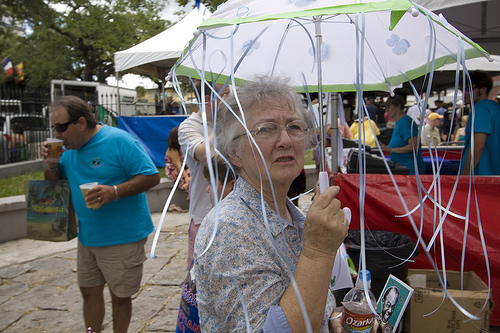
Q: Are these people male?
A: No, they are both male and female.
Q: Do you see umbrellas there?
A: Yes, there is an umbrella.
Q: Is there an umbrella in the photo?
A: Yes, there is an umbrella.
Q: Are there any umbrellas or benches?
A: Yes, there is an umbrella.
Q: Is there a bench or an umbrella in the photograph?
A: Yes, there is an umbrella.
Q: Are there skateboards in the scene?
A: No, there are no skateboards.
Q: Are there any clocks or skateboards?
A: No, there are no skateboards or clocks.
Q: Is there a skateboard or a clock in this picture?
A: No, there are no skateboards or clocks.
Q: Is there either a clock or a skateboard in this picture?
A: No, there are no skateboards or clocks.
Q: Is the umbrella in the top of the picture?
A: Yes, the umbrella is in the top of the image.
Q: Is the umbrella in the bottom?
A: No, the umbrella is in the top of the image.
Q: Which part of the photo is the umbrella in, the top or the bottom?
A: The umbrella is in the top of the image.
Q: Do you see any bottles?
A: Yes, there is a bottle.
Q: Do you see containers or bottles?
A: Yes, there is a bottle.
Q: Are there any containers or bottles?
A: Yes, there is a bottle.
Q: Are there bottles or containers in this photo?
A: Yes, there is a bottle.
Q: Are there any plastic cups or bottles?
A: Yes, there is a plastic bottle.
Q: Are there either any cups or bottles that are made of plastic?
A: Yes, the bottle is made of plastic.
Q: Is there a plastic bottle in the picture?
A: Yes, there is a bottle that is made of plastic.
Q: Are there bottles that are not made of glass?
A: Yes, there is a bottle that is made of plastic.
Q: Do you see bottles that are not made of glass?
A: Yes, there is a bottle that is made of plastic.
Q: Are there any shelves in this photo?
A: No, there are no shelves.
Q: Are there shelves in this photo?
A: No, there are no shelves.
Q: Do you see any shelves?
A: No, there are no shelves.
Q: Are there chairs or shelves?
A: No, there are no shelves or chairs.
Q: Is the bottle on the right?
A: Yes, the bottle is on the right of the image.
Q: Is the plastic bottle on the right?
A: Yes, the bottle is on the right of the image.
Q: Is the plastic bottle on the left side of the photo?
A: No, the bottle is on the right of the image.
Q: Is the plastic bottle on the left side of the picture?
A: No, the bottle is on the right of the image.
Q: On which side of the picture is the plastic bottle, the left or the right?
A: The bottle is on the right of the image.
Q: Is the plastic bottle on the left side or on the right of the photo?
A: The bottle is on the right of the image.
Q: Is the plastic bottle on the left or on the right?
A: The bottle is on the right of the image.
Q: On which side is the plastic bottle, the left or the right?
A: The bottle is on the right of the image.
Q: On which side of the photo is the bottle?
A: The bottle is on the right of the image.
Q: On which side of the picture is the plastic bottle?
A: The bottle is on the right of the image.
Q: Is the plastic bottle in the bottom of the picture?
A: Yes, the bottle is in the bottom of the image.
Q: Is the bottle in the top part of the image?
A: No, the bottle is in the bottom of the image.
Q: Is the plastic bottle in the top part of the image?
A: No, the bottle is in the bottom of the image.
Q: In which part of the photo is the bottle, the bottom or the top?
A: The bottle is in the bottom of the image.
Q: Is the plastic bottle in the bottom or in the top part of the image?
A: The bottle is in the bottom of the image.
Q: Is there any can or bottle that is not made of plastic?
A: No, there is a bottle but it is made of plastic.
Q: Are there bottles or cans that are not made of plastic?
A: No, there is a bottle but it is made of plastic.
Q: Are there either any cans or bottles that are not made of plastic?
A: No, there is a bottle but it is made of plastic.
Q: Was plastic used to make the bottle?
A: Yes, the bottle is made of plastic.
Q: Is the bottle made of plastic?
A: Yes, the bottle is made of plastic.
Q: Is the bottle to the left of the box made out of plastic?
A: Yes, the bottle is made of plastic.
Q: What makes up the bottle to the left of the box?
A: The bottle is made of plastic.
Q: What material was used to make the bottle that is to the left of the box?
A: The bottle is made of plastic.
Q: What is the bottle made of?
A: The bottle is made of plastic.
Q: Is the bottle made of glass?
A: No, the bottle is made of plastic.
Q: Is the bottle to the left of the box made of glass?
A: No, the bottle is made of plastic.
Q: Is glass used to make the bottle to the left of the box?
A: No, the bottle is made of plastic.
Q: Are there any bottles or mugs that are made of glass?
A: No, there is a bottle but it is made of plastic.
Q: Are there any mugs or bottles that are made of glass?
A: No, there is a bottle but it is made of plastic.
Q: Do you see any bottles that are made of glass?
A: No, there is a bottle but it is made of plastic.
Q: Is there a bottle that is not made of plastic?
A: No, there is a bottle but it is made of plastic.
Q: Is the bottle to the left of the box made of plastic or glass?
A: The bottle is made of plastic.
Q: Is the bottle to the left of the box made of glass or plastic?
A: The bottle is made of plastic.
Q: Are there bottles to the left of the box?
A: Yes, there is a bottle to the left of the box.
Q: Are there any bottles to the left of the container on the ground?
A: Yes, there is a bottle to the left of the box.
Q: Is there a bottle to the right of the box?
A: No, the bottle is to the left of the box.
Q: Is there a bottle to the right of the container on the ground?
A: No, the bottle is to the left of the box.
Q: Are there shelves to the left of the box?
A: No, there is a bottle to the left of the box.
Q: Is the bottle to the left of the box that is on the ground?
A: Yes, the bottle is to the left of the box.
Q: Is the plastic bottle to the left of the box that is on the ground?
A: Yes, the bottle is to the left of the box.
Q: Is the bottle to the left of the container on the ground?
A: Yes, the bottle is to the left of the box.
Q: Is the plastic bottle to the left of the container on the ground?
A: Yes, the bottle is to the left of the box.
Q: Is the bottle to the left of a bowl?
A: No, the bottle is to the left of the box.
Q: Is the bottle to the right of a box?
A: No, the bottle is to the left of a box.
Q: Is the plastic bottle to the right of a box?
A: No, the bottle is to the left of a box.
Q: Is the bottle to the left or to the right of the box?
A: The bottle is to the left of the box.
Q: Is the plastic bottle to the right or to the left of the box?
A: The bottle is to the left of the box.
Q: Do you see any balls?
A: No, there are no balls.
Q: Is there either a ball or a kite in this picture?
A: No, there are no balls or kites.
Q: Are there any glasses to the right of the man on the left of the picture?
A: Yes, there are glasses to the right of the man.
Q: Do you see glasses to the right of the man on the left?
A: Yes, there are glasses to the right of the man.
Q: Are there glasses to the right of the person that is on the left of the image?
A: Yes, there are glasses to the right of the man.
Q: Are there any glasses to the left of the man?
A: No, the glasses are to the right of the man.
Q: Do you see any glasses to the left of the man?
A: No, the glasses are to the right of the man.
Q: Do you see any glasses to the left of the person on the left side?
A: No, the glasses are to the right of the man.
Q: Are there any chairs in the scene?
A: No, there are no chairs.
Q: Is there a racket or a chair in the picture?
A: No, there are no chairs or rackets.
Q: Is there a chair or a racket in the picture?
A: No, there are no chairs or rackets.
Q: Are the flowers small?
A: Yes, the flowers are small.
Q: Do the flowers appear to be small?
A: Yes, the flowers are small.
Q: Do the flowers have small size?
A: Yes, the flowers are small.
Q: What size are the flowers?
A: The flowers are small.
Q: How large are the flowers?
A: The flowers are small.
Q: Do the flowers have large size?
A: No, the flowers are small.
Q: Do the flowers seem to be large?
A: No, the flowers are small.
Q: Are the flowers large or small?
A: The flowers are small.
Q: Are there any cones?
A: No, there are no cones.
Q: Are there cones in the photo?
A: No, there are no cones.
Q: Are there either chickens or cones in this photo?
A: No, there are no cones or chickens.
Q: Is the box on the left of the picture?
A: No, the box is on the right of the image.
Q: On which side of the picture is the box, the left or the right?
A: The box is on the right of the image.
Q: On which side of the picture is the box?
A: The box is on the right of the image.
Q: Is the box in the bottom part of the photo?
A: Yes, the box is in the bottom of the image.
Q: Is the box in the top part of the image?
A: No, the box is in the bottom of the image.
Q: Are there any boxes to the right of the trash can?
A: Yes, there is a box to the right of the trash can.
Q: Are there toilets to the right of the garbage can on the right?
A: No, there is a box to the right of the trash bin.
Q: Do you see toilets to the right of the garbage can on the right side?
A: No, there is a box to the right of the trash bin.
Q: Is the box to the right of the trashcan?
A: Yes, the box is to the right of the trashcan.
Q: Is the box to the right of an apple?
A: No, the box is to the right of the trashcan.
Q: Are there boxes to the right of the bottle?
A: Yes, there is a box to the right of the bottle.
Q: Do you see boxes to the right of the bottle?
A: Yes, there is a box to the right of the bottle.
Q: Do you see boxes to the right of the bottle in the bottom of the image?
A: Yes, there is a box to the right of the bottle.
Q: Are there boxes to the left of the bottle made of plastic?
A: No, the box is to the right of the bottle.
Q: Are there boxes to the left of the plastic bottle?
A: No, the box is to the right of the bottle.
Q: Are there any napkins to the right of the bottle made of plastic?
A: No, there is a box to the right of the bottle.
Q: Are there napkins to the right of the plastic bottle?
A: No, there is a box to the right of the bottle.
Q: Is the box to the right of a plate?
A: No, the box is to the right of the bottle.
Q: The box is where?
A: The box is on the ground.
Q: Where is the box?
A: The box is on the ground.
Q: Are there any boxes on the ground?
A: Yes, there is a box on the ground.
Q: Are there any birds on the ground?
A: No, there is a box on the ground.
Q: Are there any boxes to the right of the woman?
A: Yes, there is a box to the right of the woman.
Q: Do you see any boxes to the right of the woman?
A: Yes, there is a box to the right of the woman.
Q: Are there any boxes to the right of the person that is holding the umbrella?
A: Yes, there is a box to the right of the woman.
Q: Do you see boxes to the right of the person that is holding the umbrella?
A: Yes, there is a box to the right of the woman.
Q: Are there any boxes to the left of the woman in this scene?
A: No, the box is to the right of the woman.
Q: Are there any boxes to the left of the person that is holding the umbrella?
A: No, the box is to the right of the woman.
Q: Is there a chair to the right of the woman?
A: No, there is a box to the right of the woman.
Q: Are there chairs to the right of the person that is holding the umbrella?
A: No, there is a box to the right of the woman.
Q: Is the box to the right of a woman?
A: Yes, the box is to the right of a woman.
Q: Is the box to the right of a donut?
A: No, the box is to the right of a woman.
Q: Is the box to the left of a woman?
A: No, the box is to the right of a woman.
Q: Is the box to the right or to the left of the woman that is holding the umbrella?
A: The box is to the right of the woman.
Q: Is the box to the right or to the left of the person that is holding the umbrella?
A: The box is to the right of the woman.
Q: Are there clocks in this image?
A: No, there are no clocks.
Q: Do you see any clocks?
A: No, there are no clocks.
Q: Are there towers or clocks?
A: No, there are no clocks or towers.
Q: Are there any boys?
A: No, there are no boys.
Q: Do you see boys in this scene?
A: No, there are no boys.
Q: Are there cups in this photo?
A: Yes, there is a cup.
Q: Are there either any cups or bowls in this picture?
A: Yes, there is a cup.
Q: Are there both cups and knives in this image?
A: No, there is a cup but no knives.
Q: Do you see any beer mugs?
A: No, there are no beer mugs.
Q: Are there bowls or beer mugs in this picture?
A: No, there are no beer mugs or bowls.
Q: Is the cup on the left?
A: Yes, the cup is on the left of the image.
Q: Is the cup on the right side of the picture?
A: No, the cup is on the left of the image.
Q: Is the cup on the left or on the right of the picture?
A: The cup is on the left of the image.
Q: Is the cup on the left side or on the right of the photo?
A: The cup is on the left of the image.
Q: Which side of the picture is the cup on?
A: The cup is on the left of the image.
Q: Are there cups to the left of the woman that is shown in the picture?
A: Yes, there is a cup to the left of the woman.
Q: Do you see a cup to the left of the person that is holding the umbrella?
A: Yes, there is a cup to the left of the woman.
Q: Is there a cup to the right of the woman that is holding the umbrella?
A: No, the cup is to the left of the woman.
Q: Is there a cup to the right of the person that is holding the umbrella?
A: No, the cup is to the left of the woman.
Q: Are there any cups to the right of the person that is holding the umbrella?
A: No, the cup is to the left of the woman.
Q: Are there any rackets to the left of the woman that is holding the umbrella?
A: No, there is a cup to the left of the woman.